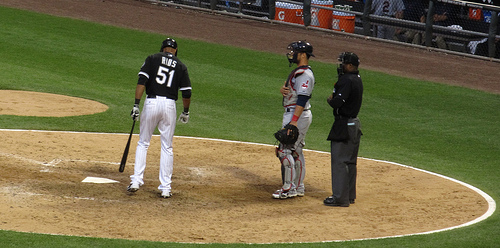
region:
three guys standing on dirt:
[106, 27, 381, 215]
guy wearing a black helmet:
[111, 17, 216, 203]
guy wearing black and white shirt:
[108, 32, 219, 204]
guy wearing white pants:
[109, 27, 206, 202]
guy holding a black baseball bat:
[108, 20, 208, 208]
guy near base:
[57, 20, 209, 217]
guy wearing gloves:
[115, 18, 212, 203]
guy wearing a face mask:
[260, 33, 321, 215]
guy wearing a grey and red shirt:
[260, 28, 322, 206]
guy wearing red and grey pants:
[264, 28, 323, 217]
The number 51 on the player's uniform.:
[153, 63, 177, 90]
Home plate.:
[76, 169, 122, 192]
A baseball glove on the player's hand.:
[270, 120, 302, 149]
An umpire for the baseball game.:
[321, 49, 369, 209]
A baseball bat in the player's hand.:
[115, 103, 142, 174]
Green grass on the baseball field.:
[13, 34, 122, 80]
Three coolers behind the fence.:
[268, 0, 363, 34]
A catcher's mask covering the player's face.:
[283, 39, 299, 66]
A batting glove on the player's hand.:
[177, 106, 191, 127]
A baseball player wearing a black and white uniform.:
[122, 34, 196, 200]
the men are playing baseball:
[92, 19, 414, 211]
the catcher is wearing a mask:
[259, 31, 322, 68]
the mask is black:
[276, 39, 302, 62]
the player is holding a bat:
[90, 26, 203, 176]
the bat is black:
[107, 102, 148, 174]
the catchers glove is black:
[255, 108, 312, 151]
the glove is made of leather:
[259, 114, 311, 157]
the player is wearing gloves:
[126, 90, 203, 136]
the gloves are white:
[118, 99, 195, 127]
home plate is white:
[58, 148, 130, 202]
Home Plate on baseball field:
[60, 162, 130, 207]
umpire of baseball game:
[316, 47, 371, 218]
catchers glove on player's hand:
[272, 121, 304, 152]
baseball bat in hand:
[111, 105, 141, 182]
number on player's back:
[151, 65, 181, 91]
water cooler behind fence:
[324, 7, 359, 35]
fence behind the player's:
[257, 3, 494, 40]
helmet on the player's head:
[275, 40, 316, 65]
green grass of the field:
[31, 55, 489, 185]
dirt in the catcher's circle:
[351, 173, 436, 232]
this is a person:
[320, 50, 367, 208]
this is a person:
[270, 37, 317, 205]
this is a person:
[127, 28, 194, 193]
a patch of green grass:
[210, 53, 250, 106]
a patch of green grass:
[372, 100, 418, 156]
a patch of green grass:
[61, 20, 108, 85]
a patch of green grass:
[16, 26, 72, 87]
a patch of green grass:
[207, 83, 267, 133]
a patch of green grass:
[460, 227, 495, 242]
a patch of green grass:
[101, 110, 131, 133]